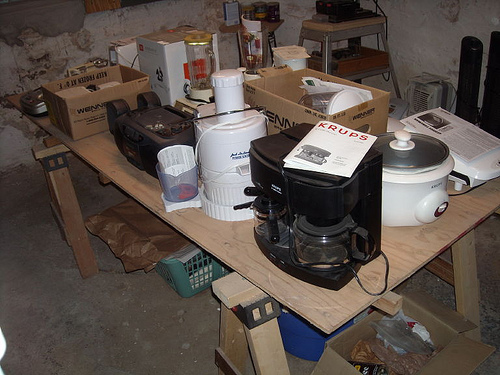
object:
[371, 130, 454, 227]
appliance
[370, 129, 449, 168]
lid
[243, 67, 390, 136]
box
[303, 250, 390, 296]
cord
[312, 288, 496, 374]
cardboard box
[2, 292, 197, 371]
floor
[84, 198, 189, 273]
clutter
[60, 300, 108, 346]
ground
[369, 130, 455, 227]
pot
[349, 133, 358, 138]
red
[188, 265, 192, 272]
holes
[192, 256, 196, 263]
holes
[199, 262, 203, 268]
holes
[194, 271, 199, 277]
holes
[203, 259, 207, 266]
holes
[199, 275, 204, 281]
holes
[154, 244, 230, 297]
basket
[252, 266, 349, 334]
scratches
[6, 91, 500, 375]
table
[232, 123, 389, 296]
coffee maker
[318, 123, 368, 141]
krups